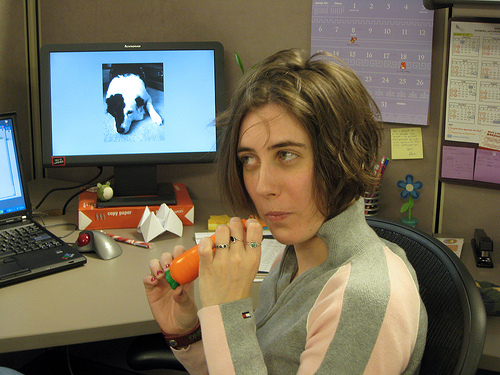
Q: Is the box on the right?
A: No, the box is on the left of the image.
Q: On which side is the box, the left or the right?
A: The box is on the left of the image.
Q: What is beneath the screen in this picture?
A: The box is beneath the screen.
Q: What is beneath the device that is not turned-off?
A: The box is beneath the screen.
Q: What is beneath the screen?
A: The box is beneath the screen.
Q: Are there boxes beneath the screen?
A: Yes, there is a box beneath the screen.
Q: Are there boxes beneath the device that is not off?
A: Yes, there is a box beneath the screen.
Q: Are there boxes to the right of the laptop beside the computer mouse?
A: Yes, there is a box to the right of the laptop computer.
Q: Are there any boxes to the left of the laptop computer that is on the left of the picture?
A: No, the box is to the right of the laptop computer.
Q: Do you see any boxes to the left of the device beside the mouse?
A: No, the box is to the right of the laptop computer.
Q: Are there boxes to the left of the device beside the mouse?
A: No, the box is to the right of the laptop computer.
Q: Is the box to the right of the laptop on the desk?
A: Yes, the box is to the right of the laptop.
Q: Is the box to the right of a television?
A: No, the box is to the right of the laptop.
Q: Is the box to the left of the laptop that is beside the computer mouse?
A: No, the box is to the right of the laptop.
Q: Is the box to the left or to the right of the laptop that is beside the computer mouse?
A: The box is to the right of the laptop.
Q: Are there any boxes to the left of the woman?
A: Yes, there is a box to the left of the woman.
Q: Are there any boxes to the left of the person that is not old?
A: Yes, there is a box to the left of the woman.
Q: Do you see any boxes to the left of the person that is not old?
A: Yes, there is a box to the left of the woman.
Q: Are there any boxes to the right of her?
A: No, the box is to the left of the woman.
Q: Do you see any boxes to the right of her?
A: No, the box is to the left of the woman.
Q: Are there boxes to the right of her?
A: No, the box is to the left of the woman.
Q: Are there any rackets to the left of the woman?
A: No, there is a box to the left of the woman.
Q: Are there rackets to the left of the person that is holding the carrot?
A: No, there is a box to the left of the woman.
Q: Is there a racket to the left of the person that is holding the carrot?
A: No, there is a box to the left of the woman.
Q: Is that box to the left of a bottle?
A: No, the box is to the left of the woman.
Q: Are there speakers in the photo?
A: No, there are no speakers.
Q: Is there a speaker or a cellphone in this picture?
A: No, there are no speakers or cell phones.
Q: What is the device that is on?
A: The device is a screen.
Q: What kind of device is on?
A: The device is a screen.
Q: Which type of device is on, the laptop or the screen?
A: The screen is on.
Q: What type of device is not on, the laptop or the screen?
A: The laptop is not on.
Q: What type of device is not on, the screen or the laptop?
A: The laptop is not on.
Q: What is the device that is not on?
A: The device is a laptop.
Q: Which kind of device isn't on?
A: The device is a laptop.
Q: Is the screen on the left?
A: Yes, the screen is on the left of the image.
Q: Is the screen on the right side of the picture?
A: No, the screen is on the left of the image.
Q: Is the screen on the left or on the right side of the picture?
A: The screen is on the left of the image.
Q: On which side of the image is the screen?
A: The screen is on the left of the image.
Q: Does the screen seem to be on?
A: Yes, the screen is on.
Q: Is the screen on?
A: Yes, the screen is on.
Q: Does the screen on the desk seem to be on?
A: Yes, the screen is on.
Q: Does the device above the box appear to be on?
A: Yes, the screen is on.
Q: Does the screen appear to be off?
A: No, the screen is on.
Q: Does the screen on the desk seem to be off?
A: No, the screen is on.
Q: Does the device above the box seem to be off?
A: No, the screen is on.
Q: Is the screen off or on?
A: The screen is on.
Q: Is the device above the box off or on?
A: The screen is on.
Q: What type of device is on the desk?
A: The device is a screen.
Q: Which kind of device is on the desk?
A: The device is a screen.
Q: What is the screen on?
A: The screen is on the desk.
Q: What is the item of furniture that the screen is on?
A: The piece of furniture is a desk.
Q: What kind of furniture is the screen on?
A: The screen is on the desk.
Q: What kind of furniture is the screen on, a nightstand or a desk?
A: The screen is on a desk.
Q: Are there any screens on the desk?
A: Yes, there is a screen on the desk.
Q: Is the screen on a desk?
A: Yes, the screen is on a desk.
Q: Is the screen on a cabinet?
A: No, the screen is on a desk.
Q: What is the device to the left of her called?
A: The device is a screen.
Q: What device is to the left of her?
A: The device is a screen.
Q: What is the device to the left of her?
A: The device is a screen.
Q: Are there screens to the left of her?
A: Yes, there is a screen to the left of the woman.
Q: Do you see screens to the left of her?
A: Yes, there is a screen to the left of the woman.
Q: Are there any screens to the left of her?
A: Yes, there is a screen to the left of the woman.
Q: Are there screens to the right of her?
A: No, the screen is to the left of the woman.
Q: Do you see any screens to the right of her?
A: No, the screen is to the left of the woman.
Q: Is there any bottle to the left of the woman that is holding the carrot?
A: No, there is a screen to the left of the woman.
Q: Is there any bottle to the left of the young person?
A: No, there is a screen to the left of the woman.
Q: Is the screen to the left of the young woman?
A: Yes, the screen is to the left of the woman.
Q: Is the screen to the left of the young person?
A: Yes, the screen is to the left of the woman.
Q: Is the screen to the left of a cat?
A: No, the screen is to the left of the woman.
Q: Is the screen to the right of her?
A: No, the screen is to the left of a woman.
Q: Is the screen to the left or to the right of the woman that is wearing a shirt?
A: The screen is to the left of the woman.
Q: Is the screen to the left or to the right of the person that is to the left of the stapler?
A: The screen is to the left of the woman.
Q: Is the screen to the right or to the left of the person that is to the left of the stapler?
A: The screen is to the left of the woman.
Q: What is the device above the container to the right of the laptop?
A: The device is a screen.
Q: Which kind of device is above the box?
A: The device is a screen.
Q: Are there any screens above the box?
A: Yes, there is a screen above the box.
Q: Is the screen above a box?
A: Yes, the screen is above a box.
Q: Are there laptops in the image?
A: Yes, there is a laptop.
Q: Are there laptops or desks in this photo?
A: Yes, there is a laptop.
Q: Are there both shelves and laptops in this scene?
A: No, there is a laptop but no shelves.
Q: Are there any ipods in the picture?
A: No, there are no ipods.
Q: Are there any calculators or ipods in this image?
A: No, there are no ipods or calculators.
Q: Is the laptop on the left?
A: Yes, the laptop is on the left of the image.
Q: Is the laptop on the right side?
A: No, the laptop is on the left of the image.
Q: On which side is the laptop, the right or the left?
A: The laptop is on the left of the image.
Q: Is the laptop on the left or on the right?
A: The laptop is on the left of the image.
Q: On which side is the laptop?
A: The laptop is on the left of the image.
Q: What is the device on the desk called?
A: The device is a laptop.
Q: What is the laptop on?
A: The laptop is on the desk.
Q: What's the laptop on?
A: The laptop is on the desk.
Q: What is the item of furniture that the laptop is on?
A: The piece of furniture is a desk.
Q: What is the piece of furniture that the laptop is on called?
A: The piece of furniture is a desk.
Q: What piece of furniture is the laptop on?
A: The laptop is on the desk.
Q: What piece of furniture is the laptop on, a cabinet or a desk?
A: The laptop is on a desk.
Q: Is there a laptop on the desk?
A: Yes, there is a laptop on the desk.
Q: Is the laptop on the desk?
A: Yes, the laptop is on the desk.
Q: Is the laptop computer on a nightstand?
A: No, the laptop computer is on the desk.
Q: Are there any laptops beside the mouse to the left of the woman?
A: Yes, there is a laptop beside the computer mouse.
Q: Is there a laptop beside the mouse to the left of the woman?
A: Yes, there is a laptop beside the computer mouse.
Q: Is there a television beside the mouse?
A: No, there is a laptop beside the mouse.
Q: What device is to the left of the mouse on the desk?
A: The device is a laptop.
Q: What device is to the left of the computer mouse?
A: The device is a laptop.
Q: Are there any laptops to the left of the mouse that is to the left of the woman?
A: Yes, there is a laptop to the left of the mouse.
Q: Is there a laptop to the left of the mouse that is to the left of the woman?
A: Yes, there is a laptop to the left of the mouse.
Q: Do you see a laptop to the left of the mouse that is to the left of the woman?
A: Yes, there is a laptop to the left of the mouse.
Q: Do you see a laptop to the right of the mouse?
A: No, the laptop is to the left of the mouse.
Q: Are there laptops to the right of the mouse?
A: No, the laptop is to the left of the mouse.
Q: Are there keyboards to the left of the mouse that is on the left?
A: No, there is a laptop to the left of the computer mouse.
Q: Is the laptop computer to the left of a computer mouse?
A: Yes, the laptop computer is to the left of a computer mouse.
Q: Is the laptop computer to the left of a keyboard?
A: No, the laptop computer is to the left of a computer mouse.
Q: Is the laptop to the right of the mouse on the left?
A: No, the laptop is to the left of the computer mouse.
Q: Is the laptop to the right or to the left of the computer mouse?
A: The laptop is to the left of the computer mouse.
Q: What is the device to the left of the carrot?
A: The device is a laptop.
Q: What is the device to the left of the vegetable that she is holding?
A: The device is a laptop.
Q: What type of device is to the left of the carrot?
A: The device is a laptop.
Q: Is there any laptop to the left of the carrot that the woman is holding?
A: Yes, there is a laptop to the left of the carrot.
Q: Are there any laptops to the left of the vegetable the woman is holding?
A: Yes, there is a laptop to the left of the carrot.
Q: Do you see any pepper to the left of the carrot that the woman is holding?
A: No, there is a laptop to the left of the carrot.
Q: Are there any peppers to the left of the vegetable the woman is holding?
A: No, there is a laptop to the left of the carrot.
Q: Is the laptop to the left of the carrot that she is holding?
A: Yes, the laptop is to the left of the carrot.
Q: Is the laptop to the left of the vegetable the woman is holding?
A: Yes, the laptop is to the left of the carrot.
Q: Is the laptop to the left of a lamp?
A: No, the laptop is to the left of the carrot.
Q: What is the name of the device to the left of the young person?
A: The device is a laptop.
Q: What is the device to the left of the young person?
A: The device is a laptop.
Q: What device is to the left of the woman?
A: The device is a laptop.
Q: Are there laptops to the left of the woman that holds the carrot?
A: Yes, there is a laptop to the left of the woman.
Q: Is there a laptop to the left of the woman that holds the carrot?
A: Yes, there is a laptop to the left of the woman.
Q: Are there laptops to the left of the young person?
A: Yes, there is a laptop to the left of the woman.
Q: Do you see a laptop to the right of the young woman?
A: No, the laptop is to the left of the woman.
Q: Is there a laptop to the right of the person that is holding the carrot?
A: No, the laptop is to the left of the woman.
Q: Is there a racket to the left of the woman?
A: No, there is a laptop to the left of the woman.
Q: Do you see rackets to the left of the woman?
A: No, there is a laptop to the left of the woman.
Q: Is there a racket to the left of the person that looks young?
A: No, there is a laptop to the left of the woman.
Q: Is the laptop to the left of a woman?
A: Yes, the laptop is to the left of a woman.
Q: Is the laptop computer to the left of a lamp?
A: No, the laptop computer is to the left of a woman.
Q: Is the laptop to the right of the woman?
A: No, the laptop is to the left of the woman.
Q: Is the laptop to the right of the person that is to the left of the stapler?
A: No, the laptop is to the left of the woman.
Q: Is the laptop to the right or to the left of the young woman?
A: The laptop is to the left of the woman.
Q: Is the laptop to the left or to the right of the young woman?
A: The laptop is to the left of the woman.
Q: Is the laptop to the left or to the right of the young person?
A: The laptop is to the left of the woman.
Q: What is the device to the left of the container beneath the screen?
A: The device is a laptop.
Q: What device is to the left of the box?
A: The device is a laptop.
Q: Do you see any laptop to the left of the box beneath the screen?
A: Yes, there is a laptop to the left of the box.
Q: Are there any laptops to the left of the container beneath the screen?
A: Yes, there is a laptop to the left of the box.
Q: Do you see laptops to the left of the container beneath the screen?
A: Yes, there is a laptop to the left of the box.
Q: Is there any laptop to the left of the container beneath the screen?
A: Yes, there is a laptop to the left of the box.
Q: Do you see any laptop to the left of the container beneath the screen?
A: Yes, there is a laptop to the left of the box.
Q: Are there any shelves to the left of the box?
A: No, there is a laptop to the left of the box.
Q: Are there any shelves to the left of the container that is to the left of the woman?
A: No, there is a laptop to the left of the box.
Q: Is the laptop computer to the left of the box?
A: Yes, the laptop computer is to the left of the box.